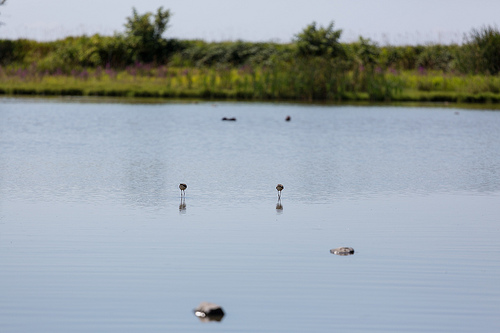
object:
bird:
[284, 115, 291, 122]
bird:
[221, 116, 236, 121]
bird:
[191, 300, 227, 325]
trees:
[293, 60, 356, 92]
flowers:
[19, 57, 184, 83]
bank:
[10, 45, 453, 122]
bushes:
[264, 20, 500, 91]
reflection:
[178, 197, 187, 215]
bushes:
[30, 5, 191, 69]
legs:
[180, 191, 185, 197]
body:
[0, 90, 496, 331]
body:
[217, 13, 289, 45]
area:
[24, 108, 147, 227]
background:
[0, 0, 500, 137]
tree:
[118, 6, 170, 63]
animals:
[178, 182, 356, 256]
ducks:
[329, 245, 356, 255]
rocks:
[15, 83, 53, 99]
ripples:
[121, 254, 234, 286]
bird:
[179, 183, 187, 208]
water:
[1, 92, 499, 331]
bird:
[275, 182, 284, 209]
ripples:
[318, 153, 468, 194]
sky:
[0, 0, 497, 44]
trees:
[290, 19, 343, 59]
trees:
[451, 31, 498, 73]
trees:
[41, 33, 110, 73]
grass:
[3, 78, 498, 97]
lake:
[0, 95, 499, 329]